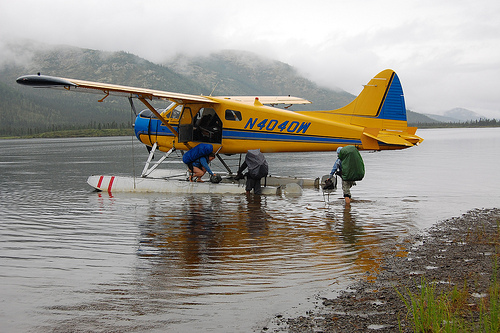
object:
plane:
[15, 69, 423, 197]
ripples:
[3, 201, 387, 292]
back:
[347, 166, 362, 183]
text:
[244, 117, 312, 133]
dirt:
[260, 208, 499, 333]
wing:
[206, 95, 312, 108]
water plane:
[16, 68, 425, 182]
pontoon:
[86, 174, 281, 196]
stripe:
[108, 176, 115, 193]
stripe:
[97, 175, 104, 188]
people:
[188, 152, 217, 182]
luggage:
[322, 179, 335, 190]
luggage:
[234, 172, 246, 180]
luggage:
[210, 173, 222, 184]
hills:
[2, 36, 499, 141]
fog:
[0, 0, 362, 94]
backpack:
[245, 149, 268, 180]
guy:
[326, 146, 357, 206]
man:
[237, 149, 269, 195]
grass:
[389, 258, 500, 333]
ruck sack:
[182, 143, 213, 165]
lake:
[0, 127, 499, 333]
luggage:
[335, 145, 365, 181]